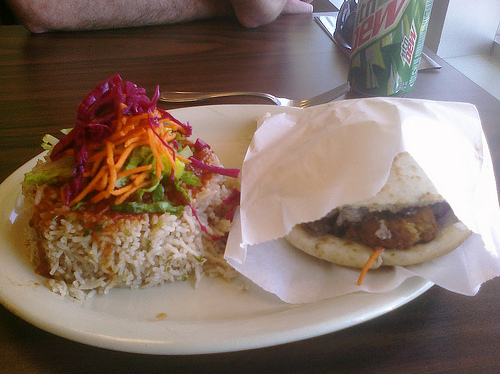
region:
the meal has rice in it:
[30, 124, 247, 289]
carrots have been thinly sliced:
[58, 120, 179, 199]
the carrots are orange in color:
[75, 108, 175, 203]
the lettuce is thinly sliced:
[33, 138, 203, 217]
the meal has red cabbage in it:
[65, 76, 149, 137]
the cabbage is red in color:
[53, 72, 170, 139]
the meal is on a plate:
[1, 100, 459, 355]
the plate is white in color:
[5, 103, 448, 358]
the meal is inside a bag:
[228, 106, 494, 296]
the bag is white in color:
[238, 95, 498, 305]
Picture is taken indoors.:
[6, 5, 490, 362]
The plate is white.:
[18, 73, 456, 345]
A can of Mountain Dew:
[315, 3, 452, 93]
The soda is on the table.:
[340, 5, 422, 104]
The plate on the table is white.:
[36, 79, 499, 324]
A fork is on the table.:
[152, 65, 354, 135]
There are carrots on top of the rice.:
[53, 65, 251, 275]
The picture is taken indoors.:
[53, 22, 489, 351]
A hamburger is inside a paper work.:
[252, 111, 422, 368]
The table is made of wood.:
[60, 55, 361, 367]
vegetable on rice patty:
[28, 123, 259, 314]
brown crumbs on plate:
[143, 296, 197, 338]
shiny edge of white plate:
[278, 331, 327, 341]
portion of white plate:
[53, 298, 253, 352]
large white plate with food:
[27, 111, 456, 326]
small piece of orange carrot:
[329, 253, 408, 285]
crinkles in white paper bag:
[331, 100, 458, 139]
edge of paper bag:
[344, 136, 435, 203]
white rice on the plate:
[38, 208, 238, 290]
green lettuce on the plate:
[50, 146, 209, 213]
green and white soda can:
[335, 15, 437, 69]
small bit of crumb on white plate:
[143, 308, 183, 328]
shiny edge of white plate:
[244, 321, 316, 354]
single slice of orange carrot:
[338, 246, 401, 288]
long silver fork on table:
[186, 78, 342, 110]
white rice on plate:
[78, 226, 188, 264]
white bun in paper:
[293, 236, 445, 274]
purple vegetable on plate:
[89, 73, 159, 118]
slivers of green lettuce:
[118, 153, 193, 205]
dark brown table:
[166, 36, 318, 76]